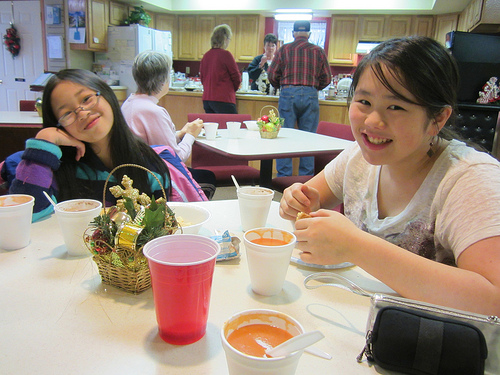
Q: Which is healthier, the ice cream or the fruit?
A: The fruit is healthier than the ice cream.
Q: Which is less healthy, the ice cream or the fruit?
A: The ice cream is less healthy than the fruit.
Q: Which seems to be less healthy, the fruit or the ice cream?
A: The ice cream is less healthy than the fruit.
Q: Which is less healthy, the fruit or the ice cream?
A: The ice cream is less healthy than the fruit.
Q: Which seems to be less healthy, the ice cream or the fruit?
A: The ice cream is less healthy than the fruit.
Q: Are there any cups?
A: Yes, there is a cup.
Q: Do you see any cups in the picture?
A: Yes, there is a cup.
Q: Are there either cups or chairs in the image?
A: Yes, there is a cup.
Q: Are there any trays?
A: No, there are no trays.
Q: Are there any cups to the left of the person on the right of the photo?
A: Yes, there is a cup to the left of the person.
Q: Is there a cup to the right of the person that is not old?
A: No, the cup is to the left of the person.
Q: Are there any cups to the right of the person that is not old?
A: No, the cup is to the left of the person.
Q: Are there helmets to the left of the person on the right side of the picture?
A: No, there is a cup to the left of the person.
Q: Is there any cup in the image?
A: Yes, there is a cup.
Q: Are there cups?
A: Yes, there is a cup.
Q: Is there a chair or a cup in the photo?
A: Yes, there is a cup.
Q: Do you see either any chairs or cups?
A: Yes, there is a cup.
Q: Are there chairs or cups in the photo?
A: Yes, there is a cup.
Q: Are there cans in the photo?
A: No, there are no cans.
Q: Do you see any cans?
A: No, there are no cans.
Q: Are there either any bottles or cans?
A: No, there are no cans or bottles.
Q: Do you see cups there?
A: Yes, there is a cup.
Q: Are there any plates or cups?
A: Yes, there is a cup.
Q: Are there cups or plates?
A: Yes, there is a cup.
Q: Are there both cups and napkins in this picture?
A: No, there is a cup but no napkins.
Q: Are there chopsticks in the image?
A: No, there are no chopsticks.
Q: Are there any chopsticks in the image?
A: No, there are no chopsticks.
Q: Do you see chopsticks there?
A: No, there are no chopsticks.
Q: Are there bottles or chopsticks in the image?
A: No, there are no chopsticks or bottles.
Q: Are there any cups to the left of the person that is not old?
A: Yes, there is a cup to the left of the person.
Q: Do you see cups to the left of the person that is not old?
A: Yes, there is a cup to the left of the person.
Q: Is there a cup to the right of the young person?
A: No, the cup is to the left of the person.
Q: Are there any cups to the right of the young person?
A: No, the cup is to the left of the person.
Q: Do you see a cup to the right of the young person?
A: No, the cup is to the left of the person.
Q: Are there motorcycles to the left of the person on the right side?
A: No, there is a cup to the left of the person.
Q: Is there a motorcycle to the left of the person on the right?
A: No, there is a cup to the left of the person.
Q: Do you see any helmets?
A: No, there are no helmets.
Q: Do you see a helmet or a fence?
A: No, there are no helmets or fences.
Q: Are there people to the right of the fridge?
A: Yes, there is a person to the right of the fridge.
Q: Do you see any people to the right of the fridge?
A: Yes, there is a person to the right of the fridge.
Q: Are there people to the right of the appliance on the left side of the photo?
A: Yes, there is a person to the right of the fridge.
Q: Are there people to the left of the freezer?
A: No, the person is to the right of the freezer.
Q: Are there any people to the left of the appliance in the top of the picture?
A: No, the person is to the right of the freezer.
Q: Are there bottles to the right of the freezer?
A: No, there is a person to the right of the freezer.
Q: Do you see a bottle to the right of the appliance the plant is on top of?
A: No, there is a person to the right of the freezer.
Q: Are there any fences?
A: No, there are no fences.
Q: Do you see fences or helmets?
A: No, there are no fences or helmets.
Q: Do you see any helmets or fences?
A: No, there are no fences or helmets.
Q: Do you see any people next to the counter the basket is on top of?
A: Yes, there is a person next to the counter.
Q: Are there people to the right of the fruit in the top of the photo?
A: Yes, there is a person to the right of the fruit.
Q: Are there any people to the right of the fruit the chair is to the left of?
A: Yes, there is a person to the right of the fruit.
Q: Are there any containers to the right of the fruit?
A: No, there is a person to the right of the fruit.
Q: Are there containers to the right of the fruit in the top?
A: No, there is a person to the right of the fruit.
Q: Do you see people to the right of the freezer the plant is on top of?
A: Yes, there is a person to the right of the fridge.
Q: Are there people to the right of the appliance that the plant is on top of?
A: Yes, there is a person to the right of the fridge.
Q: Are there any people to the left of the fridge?
A: No, the person is to the right of the fridge.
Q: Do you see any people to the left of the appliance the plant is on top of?
A: No, the person is to the right of the fridge.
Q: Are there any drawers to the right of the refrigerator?
A: No, there is a person to the right of the refrigerator.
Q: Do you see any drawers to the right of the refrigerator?
A: No, there is a person to the right of the refrigerator.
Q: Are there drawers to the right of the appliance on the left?
A: No, there is a person to the right of the refrigerator.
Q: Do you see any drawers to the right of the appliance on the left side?
A: No, there is a person to the right of the refrigerator.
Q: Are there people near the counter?
A: Yes, there is a person near the counter.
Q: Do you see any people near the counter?
A: Yes, there is a person near the counter.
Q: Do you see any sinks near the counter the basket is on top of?
A: No, there is a person near the counter.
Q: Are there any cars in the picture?
A: No, there are no cars.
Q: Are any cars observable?
A: No, there are no cars.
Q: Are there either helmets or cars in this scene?
A: No, there are no cars or helmets.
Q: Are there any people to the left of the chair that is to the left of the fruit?
A: Yes, there is a person to the left of the chair.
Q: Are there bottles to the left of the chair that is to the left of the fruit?
A: No, there is a person to the left of the chair.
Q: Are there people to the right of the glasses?
A: Yes, there is a person to the right of the glasses.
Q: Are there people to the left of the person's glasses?
A: No, the person is to the right of the glasses.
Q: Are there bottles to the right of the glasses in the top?
A: No, there is a person to the right of the glasses.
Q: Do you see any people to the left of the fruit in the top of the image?
A: Yes, there is a person to the left of the fruit.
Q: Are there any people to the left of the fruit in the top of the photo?
A: Yes, there is a person to the left of the fruit.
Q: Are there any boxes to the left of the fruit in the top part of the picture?
A: No, there is a person to the left of the fruit.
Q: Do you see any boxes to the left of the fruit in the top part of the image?
A: No, there is a person to the left of the fruit.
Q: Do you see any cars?
A: No, there are no cars.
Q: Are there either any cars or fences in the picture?
A: No, there are no cars or fences.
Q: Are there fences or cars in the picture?
A: No, there are no cars or fences.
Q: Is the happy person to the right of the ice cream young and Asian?
A: Yes, the person is young and asian.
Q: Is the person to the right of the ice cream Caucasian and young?
A: No, the person is young but asian.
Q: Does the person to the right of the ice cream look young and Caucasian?
A: No, the person is young but asian.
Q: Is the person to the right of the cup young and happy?
A: Yes, the person is young and happy.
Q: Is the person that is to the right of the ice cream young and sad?
A: No, the person is young but happy.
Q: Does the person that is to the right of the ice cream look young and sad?
A: No, the person is young but happy.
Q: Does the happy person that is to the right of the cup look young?
A: Yes, the person is young.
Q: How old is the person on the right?
A: The person is young.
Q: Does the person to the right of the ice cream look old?
A: No, the person is young.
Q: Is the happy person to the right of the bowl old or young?
A: The person is young.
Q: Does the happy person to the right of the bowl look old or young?
A: The person is young.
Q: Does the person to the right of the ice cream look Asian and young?
A: Yes, the person is Asian and young.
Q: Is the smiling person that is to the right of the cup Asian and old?
A: No, the person is Asian but young.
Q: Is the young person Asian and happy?
A: Yes, the person is Asian and happy.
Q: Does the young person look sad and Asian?
A: No, the person is Asian but happy.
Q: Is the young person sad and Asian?
A: No, the person is Asian but happy.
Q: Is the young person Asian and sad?
A: No, the person is Asian but happy.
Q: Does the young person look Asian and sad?
A: No, the person is Asian but happy.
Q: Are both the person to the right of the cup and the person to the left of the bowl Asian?
A: Yes, both the person and the person are asian.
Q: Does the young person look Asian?
A: Yes, the person is asian.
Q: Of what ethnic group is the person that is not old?
A: The person is asian.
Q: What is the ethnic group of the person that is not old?
A: The person is asian.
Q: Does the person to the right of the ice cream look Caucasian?
A: No, the person is asian.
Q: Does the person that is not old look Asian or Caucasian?
A: The person is asian.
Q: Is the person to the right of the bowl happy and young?
A: Yes, the person is happy and young.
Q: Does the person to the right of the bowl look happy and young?
A: Yes, the person is happy and young.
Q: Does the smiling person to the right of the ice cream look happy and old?
A: No, the person is happy but young.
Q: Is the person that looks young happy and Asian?
A: Yes, the person is happy and asian.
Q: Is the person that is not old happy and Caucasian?
A: No, the person is happy but asian.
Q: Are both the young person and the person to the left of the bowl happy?
A: Yes, both the person and the person are happy.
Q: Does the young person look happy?
A: Yes, the person is happy.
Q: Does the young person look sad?
A: No, the person is happy.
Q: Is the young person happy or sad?
A: The person is happy.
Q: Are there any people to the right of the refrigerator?
A: Yes, there is a person to the right of the refrigerator.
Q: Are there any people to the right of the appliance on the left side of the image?
A: Yes, there is a person to the right of the refrigerator.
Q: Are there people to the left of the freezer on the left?
A: No, the person is to the right of the freezer.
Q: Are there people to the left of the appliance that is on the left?
A: No, the person is to the right of the freezer.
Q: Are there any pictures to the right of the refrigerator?
A: No, there is a person to the right of the refrigerator.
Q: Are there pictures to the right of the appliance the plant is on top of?
A: No, there is a person to the right of the refrigerator.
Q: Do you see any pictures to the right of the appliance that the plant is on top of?
A: No, there is a person to the right of the refrigerator.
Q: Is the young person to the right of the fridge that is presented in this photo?
A: Yes, the person is to the right of the fridge.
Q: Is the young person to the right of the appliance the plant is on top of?
A: Yes, the person is to the right of the fridge.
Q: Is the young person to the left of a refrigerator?
A: No, the person is to the right of a refrigerator.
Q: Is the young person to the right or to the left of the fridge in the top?
A: The person is to the right of the refrigerator.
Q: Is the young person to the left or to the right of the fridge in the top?
A: The person is to the right of the refrigerator.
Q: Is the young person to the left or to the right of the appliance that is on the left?
A: The person is to the right of the refrigerator.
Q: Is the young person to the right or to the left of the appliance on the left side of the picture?
A: The person is to the right of the refrigerator.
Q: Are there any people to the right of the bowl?
A: Yes, there is a person to the right of the bowl.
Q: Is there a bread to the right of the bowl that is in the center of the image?
A: No, there is a person to the right of the bowl.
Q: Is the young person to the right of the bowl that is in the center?
A: Yes, the person is to the right of the bowl.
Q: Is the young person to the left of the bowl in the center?
A: No, the person is to the right of the bowl.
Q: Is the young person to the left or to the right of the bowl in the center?
A: The person is to the right of the bowl.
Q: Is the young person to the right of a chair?
A: Yes, the person is to the right of a chair.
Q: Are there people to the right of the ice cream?
A: Yes, there is a person to the right of the ice cream.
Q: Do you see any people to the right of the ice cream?
A: Yes, there is a person to the right of the ice cream.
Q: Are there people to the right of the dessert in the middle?
A: Yes, there is a person to the right of the ice cream.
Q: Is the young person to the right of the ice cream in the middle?
A: Yes, the person is to the right of the ice cream.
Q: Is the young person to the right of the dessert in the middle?
A: Yes, the person is to the right of the ice cream.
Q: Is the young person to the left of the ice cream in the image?
A: No, the person is to the right of the ice cream.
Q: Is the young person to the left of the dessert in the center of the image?
A: No, the person is to the right of the ice cream.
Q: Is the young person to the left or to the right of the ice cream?
A: The person is to the right of the ice cream.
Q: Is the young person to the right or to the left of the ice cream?
A: The person is to the right of the ice cream.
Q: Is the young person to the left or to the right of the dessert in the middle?
A: The person is to the right of the ice cream.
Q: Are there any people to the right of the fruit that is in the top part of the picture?
A: Yes, there is a person to the right of the fruit.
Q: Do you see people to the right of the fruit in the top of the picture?
A: Yes, there is a person to the right of the fruit.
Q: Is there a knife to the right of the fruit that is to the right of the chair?
A: No, there is a person to the right of the fruit.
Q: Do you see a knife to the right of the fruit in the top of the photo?
A: No, there is a person to the right of the fruit.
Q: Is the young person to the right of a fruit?
A: Yes, the person is to the right of a fruit.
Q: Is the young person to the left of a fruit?
A: No, the person is to the right of a fruit.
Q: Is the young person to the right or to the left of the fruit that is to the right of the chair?
A: The person is to the right of the fruit.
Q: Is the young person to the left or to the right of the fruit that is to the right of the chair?
A: The person is to the right of the fruit.